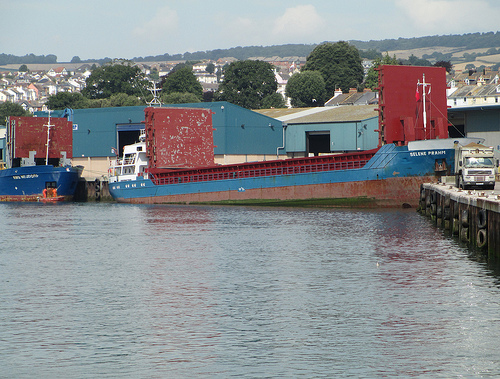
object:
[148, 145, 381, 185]
red decking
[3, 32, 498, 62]
trees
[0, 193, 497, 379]
water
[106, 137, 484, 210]
blue ship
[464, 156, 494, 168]
windshield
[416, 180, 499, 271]
bridge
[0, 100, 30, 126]
tree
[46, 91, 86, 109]
tree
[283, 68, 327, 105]
trees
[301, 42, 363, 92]
trees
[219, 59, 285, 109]
trees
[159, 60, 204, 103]
trees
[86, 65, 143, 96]
trees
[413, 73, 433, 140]
flagstaff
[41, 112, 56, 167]
flagstaff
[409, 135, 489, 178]
ship bow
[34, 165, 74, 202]
ship bow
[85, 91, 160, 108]
trees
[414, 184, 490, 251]
tires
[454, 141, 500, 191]
truck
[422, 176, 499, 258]
wooden pilings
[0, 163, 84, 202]
blue boat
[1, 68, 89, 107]
houses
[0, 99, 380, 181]
building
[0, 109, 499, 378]
port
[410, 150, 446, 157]
words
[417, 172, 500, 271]
dock